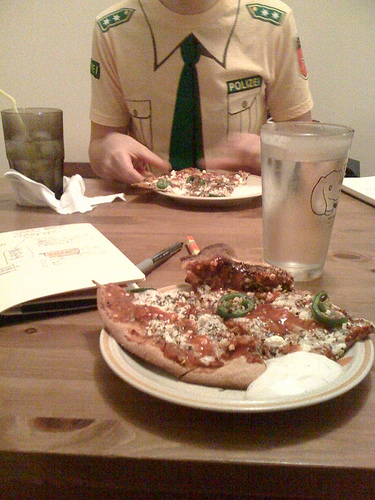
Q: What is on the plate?
A: Pizza.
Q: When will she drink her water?
A: Later.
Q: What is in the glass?
A: Ice.